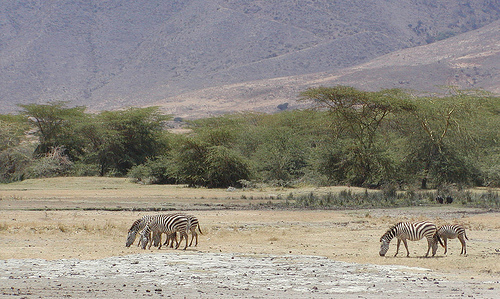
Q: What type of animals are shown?
A: Zebras.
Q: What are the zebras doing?
A: Eating.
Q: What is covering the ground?
A: Brown grass.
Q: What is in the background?
A: Mountain.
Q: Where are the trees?
A: At the base of the hill.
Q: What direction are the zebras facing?
A: Left.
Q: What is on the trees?
A: Green leaves.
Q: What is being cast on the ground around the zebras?
A: Shadows.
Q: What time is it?
A: Afternoon.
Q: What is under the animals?
A: The ground.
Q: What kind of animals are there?
A: Zebras.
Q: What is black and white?
A: Zebras.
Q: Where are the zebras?
A: On the ground.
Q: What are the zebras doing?
A: Eating.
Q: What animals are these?
A: Zebras.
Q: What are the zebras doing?
A: Grazing.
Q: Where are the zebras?
A: On a field.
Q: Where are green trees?
A: Behind the field.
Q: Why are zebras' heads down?
A: They are grazing.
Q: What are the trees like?
A: Green.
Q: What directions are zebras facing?
A: Left.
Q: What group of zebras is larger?
A: The one on the left.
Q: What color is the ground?
A: Brown.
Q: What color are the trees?
A: Green.